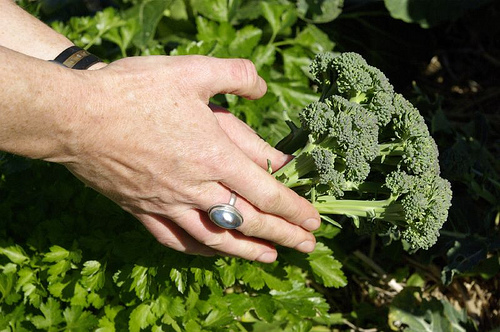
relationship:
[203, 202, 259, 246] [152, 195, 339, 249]
ring in finger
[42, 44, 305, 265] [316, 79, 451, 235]
person holding broccolli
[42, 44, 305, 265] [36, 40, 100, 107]
person has watch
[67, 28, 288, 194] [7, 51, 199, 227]
person has arm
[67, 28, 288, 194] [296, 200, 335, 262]
person has fingernails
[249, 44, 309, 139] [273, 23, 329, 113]
sunlight filtering leaves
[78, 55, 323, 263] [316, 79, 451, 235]
hands grabbing broccoli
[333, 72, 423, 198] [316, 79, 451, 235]
head of broccoli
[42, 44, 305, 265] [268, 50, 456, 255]
hands in front of broccoli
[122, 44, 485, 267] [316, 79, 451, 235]
picking a food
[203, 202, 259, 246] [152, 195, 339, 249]
ring on finger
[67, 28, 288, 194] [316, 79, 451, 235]
person holding broccoli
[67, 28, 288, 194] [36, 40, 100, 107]
person wearing watch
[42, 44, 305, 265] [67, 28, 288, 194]
hands of person